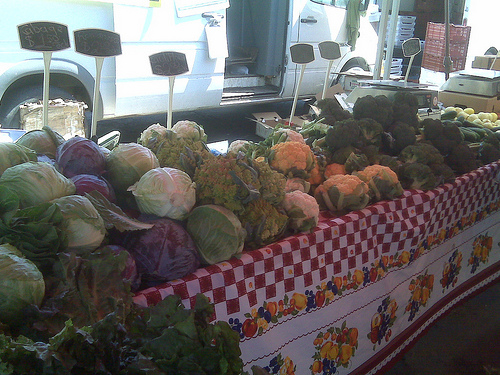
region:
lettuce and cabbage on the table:
[38, 128, 223, 276]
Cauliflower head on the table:
[315, 165, 379, 230]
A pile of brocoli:
[349, 113, 445, 182]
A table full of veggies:
[20, 125, 498, 269]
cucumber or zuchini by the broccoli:
[464, 120, 487, 152]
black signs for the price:
[12, 20, 189, 84]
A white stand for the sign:
[41, 52, 56, 127]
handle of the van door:
[205, 11, 225, 23]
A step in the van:
[224, 71, 267, 90]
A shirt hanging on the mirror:
[344, 1, 366, 57]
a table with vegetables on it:
[26, 75, 497, 336]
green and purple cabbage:
[3, 131, 293, 320]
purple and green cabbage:
[8, 125, 286, 290]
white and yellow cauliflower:
[185, 103, 440, 232]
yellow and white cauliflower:
[154, 124, 425, 243]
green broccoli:
[333, 95, 460, 192]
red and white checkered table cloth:
[201, 166, 496, 303]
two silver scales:
[354, 72, 498, 128]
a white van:
[4, 0, 405, 97]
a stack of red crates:
[404, 9, 499, 127]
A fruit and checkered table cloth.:
[162, 163, 499, 373]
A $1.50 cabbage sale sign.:
[20, 14, 69, 57]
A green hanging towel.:
[345, 0, 362, 55]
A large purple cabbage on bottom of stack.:
[120, 215, 199, 278]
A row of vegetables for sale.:
[1, 90, 496, 251]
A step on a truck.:
[222, 70, 279, 96]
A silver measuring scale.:
[442, 65, 497, 95]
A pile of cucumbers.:
[434, 109, 496, 147]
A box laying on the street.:
[240, 110, 307, 134]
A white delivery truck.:
[0, 2, 395, 112]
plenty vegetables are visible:
[85, 147, 252, 261]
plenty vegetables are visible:
[81, 175, 396, 316]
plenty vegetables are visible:
[131, 148, 342, 372]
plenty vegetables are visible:
[152, 144, 290, 271]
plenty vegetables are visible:
[121, 124, 288, 286]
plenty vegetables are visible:
[51, 68, 259, 266]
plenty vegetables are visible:
[141, 124, 293, 299]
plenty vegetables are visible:
[128, 78, 296, 340]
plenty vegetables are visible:
[151, 154, 278, 325]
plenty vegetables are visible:
[74, 95, 229, 260]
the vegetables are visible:
[37, 106, 406, 330]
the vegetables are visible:
[58, 55, 374, 373]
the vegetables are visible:
[51, 106, 254, 347]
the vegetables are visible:
[46, 102, 398, 336]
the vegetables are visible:
[24, 76, 409, 373]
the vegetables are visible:
[50, 91, 391, 371]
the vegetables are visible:
[16, 96, 321, 373]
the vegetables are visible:
[39, 121, 238, 368]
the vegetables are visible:
[45, 82, 348, 372]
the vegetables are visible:
[18, 66, 376, 361]